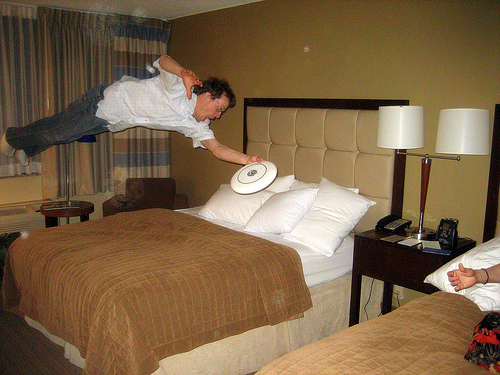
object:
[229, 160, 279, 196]
frisbee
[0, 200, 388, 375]
bed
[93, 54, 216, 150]
shirt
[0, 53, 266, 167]
man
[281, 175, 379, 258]
pillow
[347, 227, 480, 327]
table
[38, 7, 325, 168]
air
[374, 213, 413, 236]
phone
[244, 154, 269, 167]
hand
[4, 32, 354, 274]
foreground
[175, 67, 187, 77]
wristband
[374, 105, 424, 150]
lamp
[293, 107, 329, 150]
shades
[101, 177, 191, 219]
chair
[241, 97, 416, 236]
headboard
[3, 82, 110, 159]
jean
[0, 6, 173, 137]
curtain